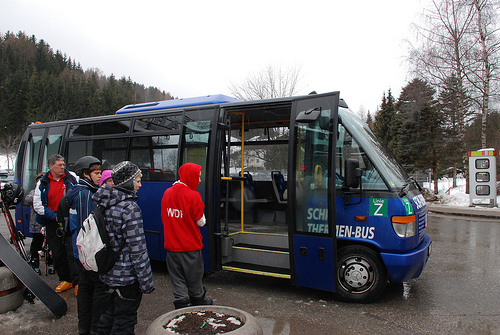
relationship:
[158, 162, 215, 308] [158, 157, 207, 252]
man wearing hoodie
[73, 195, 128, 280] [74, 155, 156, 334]
backpack on person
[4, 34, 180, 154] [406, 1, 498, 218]
hill covered in trees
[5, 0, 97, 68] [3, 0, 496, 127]
clouds in sky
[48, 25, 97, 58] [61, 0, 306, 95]
clouds in sky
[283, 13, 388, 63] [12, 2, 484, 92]
clouds in sky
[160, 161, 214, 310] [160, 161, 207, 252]
man wearing hoodie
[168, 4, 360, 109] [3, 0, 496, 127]
clouds in sky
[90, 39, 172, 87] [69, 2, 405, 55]
cloud in sky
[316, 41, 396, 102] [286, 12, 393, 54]
clouds in sky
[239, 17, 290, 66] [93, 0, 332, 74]
clouds in sky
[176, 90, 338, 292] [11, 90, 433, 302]
open door on bus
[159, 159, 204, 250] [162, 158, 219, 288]
hoodie on man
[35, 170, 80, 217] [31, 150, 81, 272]
shirt on man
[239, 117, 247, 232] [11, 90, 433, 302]
pole inside bus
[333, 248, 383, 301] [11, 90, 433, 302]
tire on bus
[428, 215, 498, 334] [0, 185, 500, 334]
moisture on road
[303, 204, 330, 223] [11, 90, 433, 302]
name on bus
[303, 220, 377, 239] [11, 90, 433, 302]
name on bus